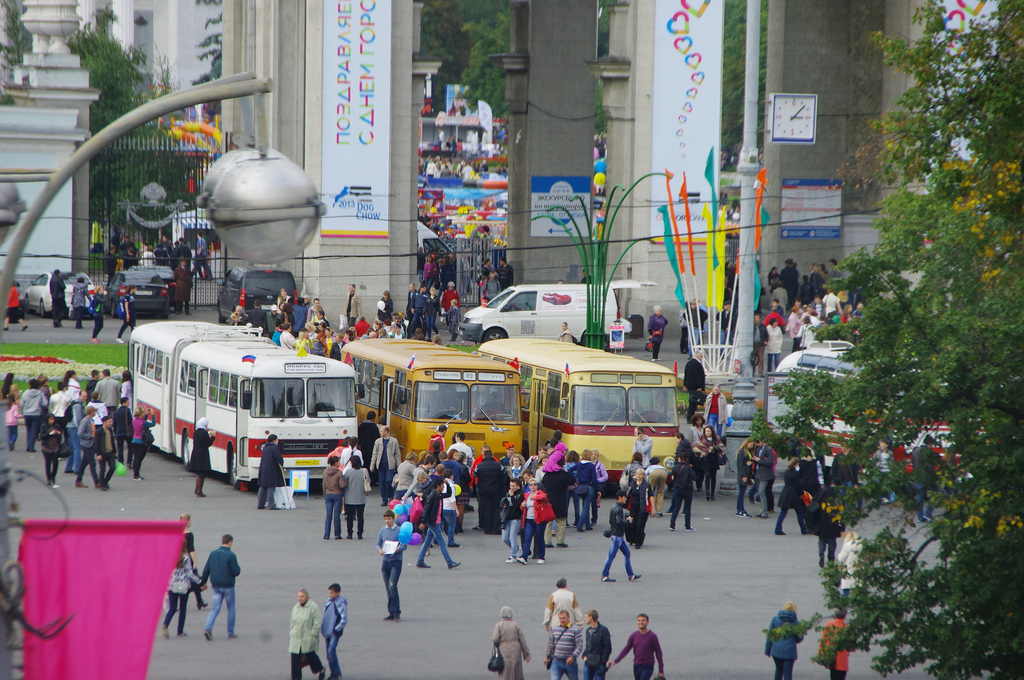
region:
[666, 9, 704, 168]
A banner on the building has a row of multicolored hearts, in graduated sizes.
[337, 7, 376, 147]
The banner on the other side of the opening has multicolored lettering.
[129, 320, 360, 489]
a white bus with a red stripe sits while passengers get on.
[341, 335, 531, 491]
A second dark yellow bus sits in the middle loading passengers.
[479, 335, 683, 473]
A third bus, light yellow with a red stripe, sits on the right.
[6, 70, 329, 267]
A streetlight has two lamps that hang over the crowds in the area.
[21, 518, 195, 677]
A plain, bright pink flag or banner hangs below the streetlight.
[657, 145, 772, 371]
Flags of teal and coral are wrapped around their flagpoles.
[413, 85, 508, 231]
A colorful crowd sits in some stands in the back of this photo.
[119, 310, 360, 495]
a large white and red bus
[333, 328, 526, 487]
a yellow bus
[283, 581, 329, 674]
person in a green coat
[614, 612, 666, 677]
man wearing a purple shirt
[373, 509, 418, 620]
man in a blue shirt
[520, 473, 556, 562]
woman wearing a red coat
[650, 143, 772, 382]
red, green and yellow flags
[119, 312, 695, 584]
crowd of people in front of three buses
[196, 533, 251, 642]
man wearing blue jeans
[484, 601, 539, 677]
woman carrying a purse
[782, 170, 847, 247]
blue sign on the building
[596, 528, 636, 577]
blue jeans on person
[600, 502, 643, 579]
person walking on street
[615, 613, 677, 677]
man walking on street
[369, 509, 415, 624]
man standing on street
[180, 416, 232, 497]
woman standing next to bus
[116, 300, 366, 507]
white bus on street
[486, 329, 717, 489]
yellow and red bus on street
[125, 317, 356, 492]
bus on the road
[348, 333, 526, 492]
the bus is parked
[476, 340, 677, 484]
the bus is yellow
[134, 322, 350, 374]
top of the bus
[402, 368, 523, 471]
front of the bus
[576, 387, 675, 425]
wind shield of bus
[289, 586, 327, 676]
a man is walking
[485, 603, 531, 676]
old lady is walking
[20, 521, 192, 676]
the flag is pink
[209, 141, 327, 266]
the light is round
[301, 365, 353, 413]
glass window on the bus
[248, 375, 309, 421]
glass window on the bus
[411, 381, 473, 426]
glass window on the bus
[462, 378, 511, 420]
glass window on the bus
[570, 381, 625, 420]
glass window on the bus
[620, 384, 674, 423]
glass window on the bus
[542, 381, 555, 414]
glass window on the bus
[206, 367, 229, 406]
glass window on the bus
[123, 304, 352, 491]
The parked white bus.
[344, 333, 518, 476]
The yellow bus parked in the middle.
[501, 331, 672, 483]
The yellow bus parked on the right.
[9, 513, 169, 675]
The pink flag hanging on the left.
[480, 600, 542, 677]
The older woman in the trench coat.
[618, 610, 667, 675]
The man walking in a purple shirt.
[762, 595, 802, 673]
The woman walking with a blue coat.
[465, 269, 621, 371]
The white van.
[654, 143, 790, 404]
The group of colorful flags.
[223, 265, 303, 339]
The black family van.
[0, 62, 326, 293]
street light and pole over the street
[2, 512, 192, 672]
pink flag attached to a light pole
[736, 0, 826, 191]
clock displayed on a metal pole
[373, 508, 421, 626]
man in grey with blue balloons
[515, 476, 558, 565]
lady in a red jacket and jeans